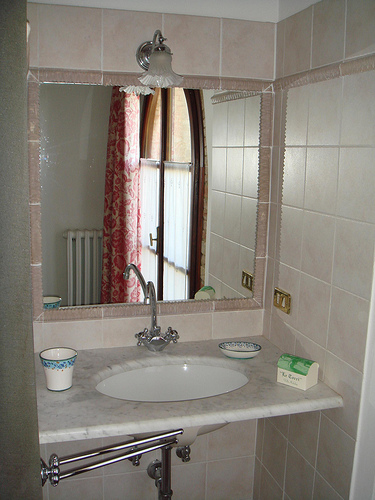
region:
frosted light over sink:
[125, 38, 185, 96]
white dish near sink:
[209, 335, 289, 390]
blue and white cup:
[44, 328, 83, 407]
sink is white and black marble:
[51, 404, 251, 429]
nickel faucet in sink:
[131, 278, 173, 346]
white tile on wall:
[318, 148, 374, 298]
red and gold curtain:
[97, 114, 158, 306]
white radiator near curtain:
[62, 233, 93, 299]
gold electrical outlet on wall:
[267, 283, 296, 323]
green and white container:
[272, 352, 315, 389]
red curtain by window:
[101, 81, 159, 329]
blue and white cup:
[40, 344, 72, 389]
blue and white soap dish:
[219, 335, 256, 360]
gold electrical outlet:
[255, 296, 305, 314]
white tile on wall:
[276, 140, 364, 333]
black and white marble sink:
[85, 388, 283, 426]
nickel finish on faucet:
[130, 270, 192, 357]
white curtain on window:
[124, 143, 210, 296]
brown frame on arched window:
[122, 82, 221, 252]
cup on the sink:
[39, 347, 78, 390]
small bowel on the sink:
[218, 341, 261, 359]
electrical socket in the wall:
[272, 285, 291, 314]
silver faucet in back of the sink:
[122, 260, 157, 338]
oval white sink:
[94, 364, 251, 402]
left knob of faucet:
[134, 326, 152, 346]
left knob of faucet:
[163, 326, 180, 345]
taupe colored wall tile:
[31, 154, 373, 498]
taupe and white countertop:
[31, 334, 345, 443]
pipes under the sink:
[148, 429, 176, 497]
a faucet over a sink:
[116, 258, 163, 324]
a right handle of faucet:
[160, 322, 182, 348]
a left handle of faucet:
[131, 323, 151, 353]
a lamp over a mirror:
[129, 20, 190, 95]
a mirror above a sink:
[32, 62, 276, 332]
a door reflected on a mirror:
[135, 86, 206, 299]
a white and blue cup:
[35, 342, 77, 391]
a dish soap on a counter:
[214, 334, 263, 359]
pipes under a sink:
[38, 429, 193, 496]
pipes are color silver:
[48, 436, 195, 489]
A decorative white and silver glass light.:
[132, 28, 188, 93]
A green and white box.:
[274, 352, 321, 392]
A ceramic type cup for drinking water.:
[39, 347, 79, 392]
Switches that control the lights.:
[272, 287, 290, 317]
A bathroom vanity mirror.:
[30, 82, 258, 311]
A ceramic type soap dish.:
[221, 339, 262, 357]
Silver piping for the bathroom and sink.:
[42, 426, 193, 498]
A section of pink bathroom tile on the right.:
[266, 2, 374, 354]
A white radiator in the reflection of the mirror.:
[62, 229, 106, 306]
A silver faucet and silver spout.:
[135, 282, 179, 352]